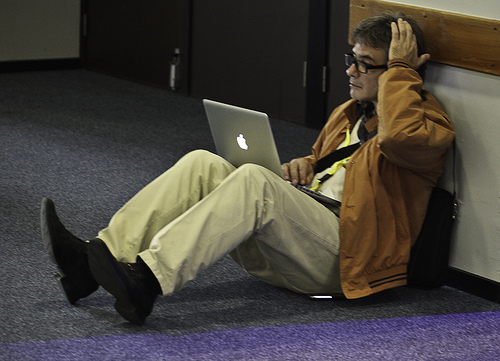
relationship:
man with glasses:
[39, 10, 459, 328] [343, 52, 388, 74]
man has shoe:
[39, 10, 459, 328] [91, 237, 160, 327]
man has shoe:
[39, 10, 459, 328] [39, 197, 100, 305]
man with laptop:
[39, 10, 459, 328] [201, 98, 342, 207]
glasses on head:
[343, 52, 388, 74] [344, 10, 426, 102]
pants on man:
[95, 148, 342, 301] [39, 10, 459, 328]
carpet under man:
[2, 70, 500, 360] [39, 10, 459, 328]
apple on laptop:
[236, 135, 248, 152] [201, 98, 342, 207]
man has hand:
[39, 10, 459, 328] [388, 18, 430, 66]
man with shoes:
[39, 10, 459, 328] [40, 196, 160, 331]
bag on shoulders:
[407, 187, 458, 290] [417, 89, 458, 169]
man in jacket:
[39, 10, 459, 328] [306, 59, 455, 299]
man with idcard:
[39, 10, 459, 328] [304, 179, 329, 190]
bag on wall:
[407, 187, 458, 290] [349, 0, 500, 303]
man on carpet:
[39, 10, 459, 328] [2, 70, 500, 360]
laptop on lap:
[201, 98, 342, 207] [205, 146, 349, 274]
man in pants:
[39, 10, 459, 328] [95, 148, 342, 301]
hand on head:
[388, 18, 430, 66] [344, 10, 426, 102]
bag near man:
[407, 187, 458, 290] [39, 10, 459, 328]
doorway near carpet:
[80, 0, 349, 131] [2, 70, 500, 360]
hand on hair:
[388, 18, 430, 66] [353, 9, 428, 80]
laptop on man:
[201, 98, 342, 207] [39, 10, 459, 328]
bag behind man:
[407, 187, 458, 290] [39, 10, 459, 328]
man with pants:
[39, 10, 459, 328] [95, 148, 342, 301]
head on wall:
[344, 10, 426, 102] [349, 0, 500, 303]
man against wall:
[39, 10, 459, 328] [349, 0, 500, 303]